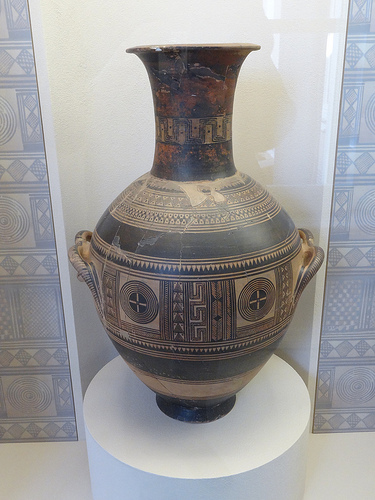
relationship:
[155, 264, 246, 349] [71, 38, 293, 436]
design on vase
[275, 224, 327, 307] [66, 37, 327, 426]
handle on pot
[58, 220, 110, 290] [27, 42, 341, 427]
handle on vase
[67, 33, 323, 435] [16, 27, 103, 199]
artifact in museum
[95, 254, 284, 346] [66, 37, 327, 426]
patterns on pot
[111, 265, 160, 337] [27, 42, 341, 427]
patterns on vase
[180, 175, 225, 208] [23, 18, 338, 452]
spots on vase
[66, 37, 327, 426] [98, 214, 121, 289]
pot has crack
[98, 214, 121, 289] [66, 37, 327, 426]
crack on pot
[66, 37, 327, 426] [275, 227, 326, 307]
pot has handle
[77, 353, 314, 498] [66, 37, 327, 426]
pedestal holding pot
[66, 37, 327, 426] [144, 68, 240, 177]
pot has neck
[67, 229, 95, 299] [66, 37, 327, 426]
handle on pot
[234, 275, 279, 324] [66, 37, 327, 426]
circle on pot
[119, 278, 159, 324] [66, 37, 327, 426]
circle on pot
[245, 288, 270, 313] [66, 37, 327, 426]
cross on pot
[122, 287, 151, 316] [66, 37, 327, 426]
cross on pot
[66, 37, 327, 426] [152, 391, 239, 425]
pot has base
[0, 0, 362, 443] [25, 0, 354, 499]
wall has display case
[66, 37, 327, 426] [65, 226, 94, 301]
pot has handle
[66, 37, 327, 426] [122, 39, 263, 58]
pot has opening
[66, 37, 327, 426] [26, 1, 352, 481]
pot behind glass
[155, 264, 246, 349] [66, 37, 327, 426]
design on pot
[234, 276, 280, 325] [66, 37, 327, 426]
design on pot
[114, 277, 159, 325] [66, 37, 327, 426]
circle on pot